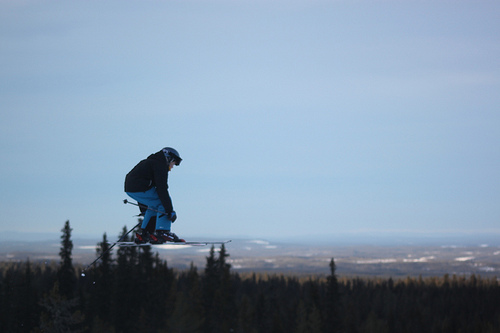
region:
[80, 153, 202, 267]
person is on skis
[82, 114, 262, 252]
person is in air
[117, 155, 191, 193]
person has black coat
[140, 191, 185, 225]
person has blue pants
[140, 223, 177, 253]
person has black shoes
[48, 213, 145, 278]
person holds black ski poles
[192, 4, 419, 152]
sky is blue and clear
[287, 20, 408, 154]
no clouds in sky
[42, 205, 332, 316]
green trees behind person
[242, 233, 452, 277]
brown ground in distance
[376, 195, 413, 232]
part of a cloud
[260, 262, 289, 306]
part of a forest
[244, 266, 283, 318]
part of a forest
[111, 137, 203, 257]
this is a man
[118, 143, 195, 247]
the man is on air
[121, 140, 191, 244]
the man is skating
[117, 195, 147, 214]
this is a pole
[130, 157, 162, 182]
this is a jacket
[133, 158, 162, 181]
the jacket is black in color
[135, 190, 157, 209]
the trousers are blue in color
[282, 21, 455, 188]
this is the sky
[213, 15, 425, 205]
the sky is blue in color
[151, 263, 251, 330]
these are the trees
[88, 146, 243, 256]
a person wearing a pair of skis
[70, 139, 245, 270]
a person flying through the air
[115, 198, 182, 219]
a grey ski pole in aperson's hand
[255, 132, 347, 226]
clear blue skies over the scene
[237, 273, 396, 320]
trees growing next to the ski slope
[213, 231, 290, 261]
snowy hills in the distance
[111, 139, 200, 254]
a person wearing a black jacket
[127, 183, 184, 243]
the person's blue snow pants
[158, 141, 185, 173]
the person's grey helmet and black goggles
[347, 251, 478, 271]
patches of snow on the land